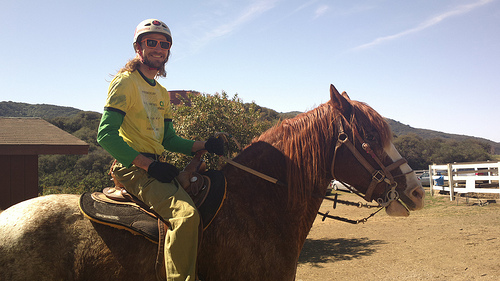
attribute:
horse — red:
[2, 80, 431, 280]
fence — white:
[421, 156, 499, 206]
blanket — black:
[77, 206, 221, 248]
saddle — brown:
[81, 176, 223, 208]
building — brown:
[1, 114, 86, 195]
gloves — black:
[136, 136, 230, 180]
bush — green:
[164, 84, 265, 171]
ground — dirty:
[314, 212, 499, 277]